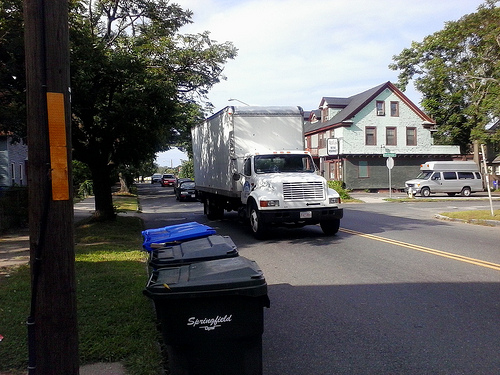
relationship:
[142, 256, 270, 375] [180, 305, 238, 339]
trash can has white letters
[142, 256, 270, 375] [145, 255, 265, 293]
trash can with lids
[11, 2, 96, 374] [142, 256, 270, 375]
pole close to trash can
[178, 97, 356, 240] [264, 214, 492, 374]
truck on road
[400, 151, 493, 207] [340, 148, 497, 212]
van on side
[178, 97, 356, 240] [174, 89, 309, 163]
van has big box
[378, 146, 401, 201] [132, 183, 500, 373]
sign in street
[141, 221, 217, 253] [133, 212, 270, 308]
trash can with lids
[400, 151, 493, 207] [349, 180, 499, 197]
van in parking lot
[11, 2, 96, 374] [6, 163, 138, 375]
telephone pole on side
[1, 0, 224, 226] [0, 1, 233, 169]
tree with green leaves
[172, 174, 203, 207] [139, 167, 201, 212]
car coming down street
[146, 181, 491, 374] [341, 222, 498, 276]
street hs two lanes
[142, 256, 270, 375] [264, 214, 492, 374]
trash can on road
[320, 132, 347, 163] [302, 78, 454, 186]
sign of business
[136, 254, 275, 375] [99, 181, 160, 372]
trash can on street curb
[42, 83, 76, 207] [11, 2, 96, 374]
gold flag on pole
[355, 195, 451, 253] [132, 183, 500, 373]
shadow on street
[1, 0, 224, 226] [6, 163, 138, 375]
tree on sidewalk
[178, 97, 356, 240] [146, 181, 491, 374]
truck on street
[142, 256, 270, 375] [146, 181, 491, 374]
trash can on street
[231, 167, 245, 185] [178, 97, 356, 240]
mirror on vehicle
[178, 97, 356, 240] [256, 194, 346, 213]
vehicle front headlight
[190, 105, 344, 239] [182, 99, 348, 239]
truck has licence plate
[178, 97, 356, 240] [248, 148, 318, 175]
vehicle front windshield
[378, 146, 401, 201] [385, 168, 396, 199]
sign on pole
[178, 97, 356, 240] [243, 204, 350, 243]
vehicle has front wheels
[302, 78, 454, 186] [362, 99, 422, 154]
building has windows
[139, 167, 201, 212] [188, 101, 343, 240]
cars behind truck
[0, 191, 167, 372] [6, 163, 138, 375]
grass on sidewalk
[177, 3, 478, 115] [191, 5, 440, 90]
cloud in sky